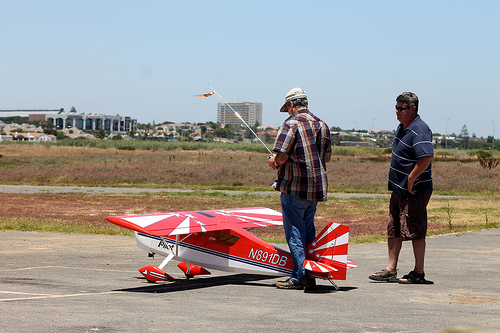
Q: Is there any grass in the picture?
A: Yes, there is grass.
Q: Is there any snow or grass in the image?
A: Yes, there is grass.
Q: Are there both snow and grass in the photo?
A: No, there is grass but no snow.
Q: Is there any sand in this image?
A: No, there is no sand.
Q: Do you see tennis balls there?
A: No, there are no tennis balls.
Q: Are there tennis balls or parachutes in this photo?
A: No, there are no tennis balls or parachutes.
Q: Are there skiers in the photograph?
A: No, there are no skiers.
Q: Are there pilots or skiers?
A: No, there are no skiers or pilots.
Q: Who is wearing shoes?
A: The man is wearing shoes.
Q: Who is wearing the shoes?
A: The man is wearing shoes.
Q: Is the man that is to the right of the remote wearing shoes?
A: Yes, the man is wearing shoes.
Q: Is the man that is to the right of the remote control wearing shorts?
A: No, the man is wearing shoes.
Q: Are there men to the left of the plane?
A: No, the man is to the right of the plane.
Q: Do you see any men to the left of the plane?
A: No, the man is to the right of the plane.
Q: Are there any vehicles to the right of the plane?
A: No, there is a man to the right of the plane.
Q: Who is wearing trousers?
A: The man is wearing trousers.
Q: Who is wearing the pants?
A: The man is wearing trousers.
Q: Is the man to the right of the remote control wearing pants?
A: Yes, the man is wearing pants.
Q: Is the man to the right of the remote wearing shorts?
A: No, the man is wearing pants.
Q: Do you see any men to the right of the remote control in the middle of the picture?
A: Yes, there is a man to the right of the remote control.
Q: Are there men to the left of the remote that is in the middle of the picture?
A: No, the man is to the right of the remote.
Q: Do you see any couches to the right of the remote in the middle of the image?
A: No, there is a man to the right of the remote.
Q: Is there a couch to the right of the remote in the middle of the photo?
A: No, there is a man to the right of the remote.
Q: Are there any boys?
A: No, there are no boys.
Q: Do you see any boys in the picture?
A: No, there are no boys.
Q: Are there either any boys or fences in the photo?
A: No, there are no boys or fences.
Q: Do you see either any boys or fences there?
A: No, there are no boys or fences.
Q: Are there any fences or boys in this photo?
A: No, there are no boys or fences.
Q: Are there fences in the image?
A: No, there are no fences.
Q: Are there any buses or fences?
A: No, there are no fences or buses.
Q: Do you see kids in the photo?
A: No, there are no kids.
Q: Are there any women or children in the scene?
A: No, there are no children or women.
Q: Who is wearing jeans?
A: The man is wearing jeans.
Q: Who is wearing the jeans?
A: The man is wearing jeans.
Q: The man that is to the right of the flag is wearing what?
A: The man is wearing jeans.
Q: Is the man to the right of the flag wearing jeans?
A: Yes, the man is wearing jeans.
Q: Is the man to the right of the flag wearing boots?
A: No, the man is wearing jeans.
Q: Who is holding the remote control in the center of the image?
A: The man is holding the remote control.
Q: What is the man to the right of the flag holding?
A: The man is holding the remote control.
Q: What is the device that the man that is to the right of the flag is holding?
A: The device is a remote control.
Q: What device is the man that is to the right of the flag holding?
A: The man is holding the remote control.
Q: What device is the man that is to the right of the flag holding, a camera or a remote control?
A: The man is holding a remote control.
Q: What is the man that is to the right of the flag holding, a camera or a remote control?
A: The man is holding a remote control.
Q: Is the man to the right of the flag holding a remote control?
A: Yes, the man is holding a remote control.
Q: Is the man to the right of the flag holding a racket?
A: No, the man is holding a remote control.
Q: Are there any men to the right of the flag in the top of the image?
A: Yes, there is a man to the right of the flag.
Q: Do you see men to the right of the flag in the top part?
A: Yes, there is a man to the right of the flag.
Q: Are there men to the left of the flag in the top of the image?
A: No, the man is to the right of the flag.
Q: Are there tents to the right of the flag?
A: No, there is a man to the right of the flag.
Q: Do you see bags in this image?
A: No, there are no bags.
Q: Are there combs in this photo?
A: No, there are no combs.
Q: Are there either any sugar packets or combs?
A: No, there are no combs or sugar packets.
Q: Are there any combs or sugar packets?
A: No, there are no combs or sugar packets.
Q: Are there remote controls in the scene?
A: Yes, there is a remote control.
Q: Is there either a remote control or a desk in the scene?
A: Yes, there is a remote control.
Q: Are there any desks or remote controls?
A: Yes, there is a remote control.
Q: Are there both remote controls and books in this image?
A: No, there is a remote control but no books.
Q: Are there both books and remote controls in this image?
A: No, there is a remote control but no books.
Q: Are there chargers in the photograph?
A: No, there are no chargers.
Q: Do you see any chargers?
A: No, there are no chargers.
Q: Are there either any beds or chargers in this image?
A: No, there are no chargers or beds.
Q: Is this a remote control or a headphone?
A: This is a remote control.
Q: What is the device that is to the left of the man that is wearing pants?
A: The device is a remote control.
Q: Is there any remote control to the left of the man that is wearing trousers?
A: Yes, there is a remote control to the left of the man.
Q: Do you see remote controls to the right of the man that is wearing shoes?
A: No, the remote control is to the left of the man.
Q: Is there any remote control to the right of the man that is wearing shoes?
A: No, the remote control is to the left of the man.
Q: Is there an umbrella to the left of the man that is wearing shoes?
A: No, there is a remote control to the left of the man.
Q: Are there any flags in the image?
A: Yes, there is a flag.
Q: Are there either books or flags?
A: Yes, there is a flag.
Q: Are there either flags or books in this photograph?
A: Yes, there is a flag.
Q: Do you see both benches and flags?
A: No, there is a flag but no benches.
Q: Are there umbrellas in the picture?
A: No, there are no umbrellas.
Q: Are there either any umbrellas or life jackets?
A: No, there are no umbrellas or life jackets.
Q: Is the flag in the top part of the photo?
A: Yes, the flag is in the top of the image.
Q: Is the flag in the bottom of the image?
A: No, the flag is in the top of the image.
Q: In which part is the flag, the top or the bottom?
A: The flag is in the top of the image.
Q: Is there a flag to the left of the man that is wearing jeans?
A: Yes, there is a flag to the left of the man.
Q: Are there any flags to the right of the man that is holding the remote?
A: No, the flag is to the left of the man.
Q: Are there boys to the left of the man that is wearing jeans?
A: No, there is a flag to the left of the man.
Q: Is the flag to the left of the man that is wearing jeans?
A: Yes, the flag is to the left of the man.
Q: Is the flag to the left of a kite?
A: No, the flag is to the left of the man.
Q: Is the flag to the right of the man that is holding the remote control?
A: No, the flag is to the left of the man.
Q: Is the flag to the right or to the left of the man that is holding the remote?
A: The flag is to the left of the man.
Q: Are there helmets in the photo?
A: No, there are no helmets.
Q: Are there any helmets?
A: No, there are no helmets.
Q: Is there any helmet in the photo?
A: No, there are no helmets.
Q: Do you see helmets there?
A: No, there are no helmets.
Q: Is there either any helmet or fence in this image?
A: No, there are no helmets or fences.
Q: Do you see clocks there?
A: No, there are no clocks.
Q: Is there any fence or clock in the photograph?
A: No, there are no clocks or fences.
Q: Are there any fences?
A: No, there are no fences.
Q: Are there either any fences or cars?
A: No, there are no fences or cars.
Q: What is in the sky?
A: The clouds are in the sky.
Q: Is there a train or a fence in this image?
A: No, there are no fences or trains.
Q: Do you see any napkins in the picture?
A: No, there are no napkins.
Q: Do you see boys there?
A: No, there are no boys.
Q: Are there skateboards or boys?
A: No, there are no boys or skateboards.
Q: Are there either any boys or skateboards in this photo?
A: No, there are no boys or skateboards.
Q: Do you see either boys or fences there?
A: No, there are no boys or fences.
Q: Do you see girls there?
A: No, there are no girls.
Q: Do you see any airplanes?
A: Yes, there is an airplane.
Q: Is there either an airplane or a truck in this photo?
A: Yes, there is an airplane.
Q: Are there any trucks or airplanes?
A: Yes, there is an airplane.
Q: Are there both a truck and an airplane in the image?
A: No, there is an airplane but no trucks.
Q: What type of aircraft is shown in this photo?
A: The aircraft is an airplane.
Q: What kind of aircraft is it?
A: The aircraft is an airplane.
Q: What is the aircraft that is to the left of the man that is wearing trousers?
A: The aircraft is an airplane.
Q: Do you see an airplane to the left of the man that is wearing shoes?
A: Yes, there is an airplane to the left of the man.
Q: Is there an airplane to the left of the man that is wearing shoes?
A: Yes, there is an airplane to the left of the man.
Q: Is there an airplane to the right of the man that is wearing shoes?
A: No, the airplane is to the left of the man.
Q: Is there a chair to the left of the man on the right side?
A: No, there is an airplane to the left of the man.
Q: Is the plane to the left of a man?
A: Yes, the plane is to the left of a man.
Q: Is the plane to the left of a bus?
A: No, the plane is to the left of a man.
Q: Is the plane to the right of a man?
A: No, the plane is to the left of a man.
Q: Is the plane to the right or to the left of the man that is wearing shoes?
A: The plane is to the left of the man.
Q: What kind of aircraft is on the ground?
A: The aircraft is an airplane.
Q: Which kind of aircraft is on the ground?
A: The aircraft is an airplane.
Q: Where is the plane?
A: The plane is on the ground.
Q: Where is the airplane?
A: The plane is on the ground.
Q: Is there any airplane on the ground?
A: Yes, there is an airplane on the ground.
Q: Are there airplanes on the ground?
A: Yes, there is an airplane on the ground.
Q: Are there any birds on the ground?
A: No, there is an airplane on the ground.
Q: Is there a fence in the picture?
A: No, there are no fences.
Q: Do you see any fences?
A: No, there are no fences.